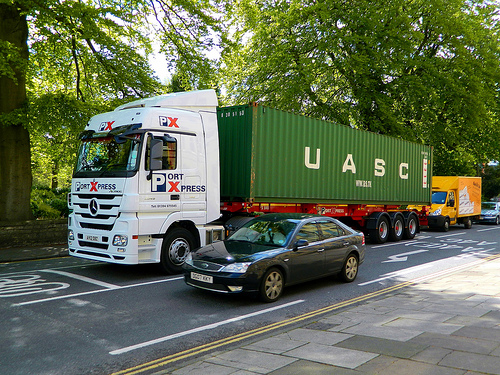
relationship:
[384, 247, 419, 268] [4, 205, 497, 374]
arrow painted on road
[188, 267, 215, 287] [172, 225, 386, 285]
license plate on car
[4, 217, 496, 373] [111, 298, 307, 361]
line on road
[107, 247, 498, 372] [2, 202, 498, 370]
lines on pavement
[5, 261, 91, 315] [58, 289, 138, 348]
symbol on road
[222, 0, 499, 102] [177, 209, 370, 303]
tree behind car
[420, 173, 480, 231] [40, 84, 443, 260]
van behind big truck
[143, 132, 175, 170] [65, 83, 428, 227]
mirror on truck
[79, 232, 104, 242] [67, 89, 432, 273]
license plate on truck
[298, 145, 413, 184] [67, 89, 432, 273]
uasc on truck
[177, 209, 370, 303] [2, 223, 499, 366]
car on street